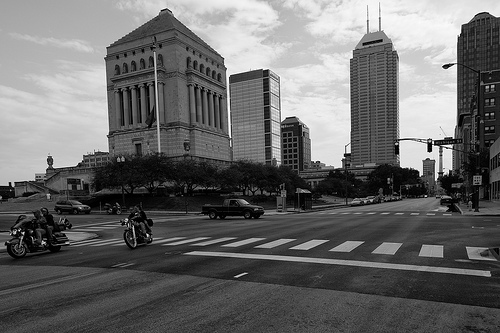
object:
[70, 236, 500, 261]
crosswalk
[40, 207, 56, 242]
woman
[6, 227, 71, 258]
motorcycle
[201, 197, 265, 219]
truck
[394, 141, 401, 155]
traffic light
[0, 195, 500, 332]
street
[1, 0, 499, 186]
sky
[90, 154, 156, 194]
tree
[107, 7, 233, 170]
building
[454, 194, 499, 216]
sidewalk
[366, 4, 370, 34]
antenna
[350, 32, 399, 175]
building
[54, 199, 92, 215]
suv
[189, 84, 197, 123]
column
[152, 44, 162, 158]
flag pole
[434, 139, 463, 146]
street sign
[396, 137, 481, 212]
pole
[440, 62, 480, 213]
street light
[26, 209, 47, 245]
man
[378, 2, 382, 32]
antenna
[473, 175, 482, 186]
street sign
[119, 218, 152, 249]
motorcycle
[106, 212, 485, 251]
intersection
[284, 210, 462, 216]
crosswalk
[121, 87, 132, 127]
column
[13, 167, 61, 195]
steps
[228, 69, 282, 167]
building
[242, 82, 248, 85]
windows.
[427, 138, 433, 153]
traffic light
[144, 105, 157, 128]
flag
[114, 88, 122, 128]
column